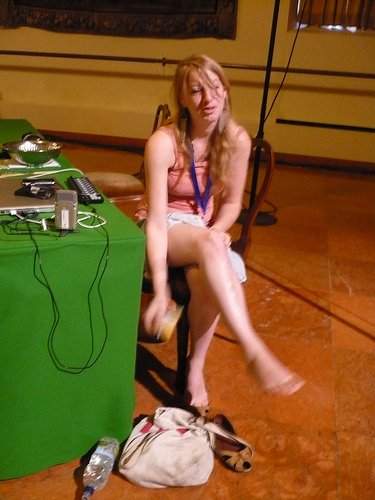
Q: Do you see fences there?
A: No, there are no fences.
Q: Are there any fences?
A: No, there are no fences.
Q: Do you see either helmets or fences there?
A: No, there are no fences or helmets.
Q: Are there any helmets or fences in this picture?
A: No, there are no fences or helmets.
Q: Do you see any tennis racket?
A: No, there are no rackets.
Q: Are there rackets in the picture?
A: No, there are no rackets.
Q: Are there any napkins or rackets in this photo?
A: No, there are no rackets or napkins.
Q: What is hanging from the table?
A: The cable is hanging from the table.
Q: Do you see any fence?
A: No, there are no fences.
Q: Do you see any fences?
A: No, there are no fences.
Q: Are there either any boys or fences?
A: No, there are no fences or boys.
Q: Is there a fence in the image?
A: No, there are no fences.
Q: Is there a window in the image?
A: Yes, there is a window.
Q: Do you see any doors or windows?
A: Yes, there is a window.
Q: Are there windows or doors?
A: Yes, there is a window.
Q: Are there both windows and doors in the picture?
A: No, there is a window but no doors.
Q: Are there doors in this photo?
A: No, there are no doors.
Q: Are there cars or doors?
A: No, there are no doors or cars.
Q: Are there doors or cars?
A: No, there are no doors or cars.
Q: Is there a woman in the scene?
A: Yes, there is a woman.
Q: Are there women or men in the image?
A: Yes, there is a woman.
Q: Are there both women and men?
A: No, there is a woman but no men.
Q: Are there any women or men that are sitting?
A: Yes, the woman is sitting.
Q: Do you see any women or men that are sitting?
A: Yes, the woman is sitting.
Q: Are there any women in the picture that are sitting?
A: Yes, there is a woman that is sitting.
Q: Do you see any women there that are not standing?
A: Yes, there is a woman that is sitting .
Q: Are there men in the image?
A: No, there are no men.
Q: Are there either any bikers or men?
A: No, there are no men or bikers.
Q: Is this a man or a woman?
A: This is a woman.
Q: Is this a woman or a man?
A: This is a woman.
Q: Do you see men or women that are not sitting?
A: No, there is a woman but she is sitting.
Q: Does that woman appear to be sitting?
A: Yes, the woman is sitting.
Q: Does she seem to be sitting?
A: Yes, the woman is sitting.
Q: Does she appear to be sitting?
A: Yes, the woman is sitting.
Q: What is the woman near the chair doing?
A: The woman is sitting.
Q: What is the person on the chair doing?
A: The woman is sitting.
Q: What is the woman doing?
A: The woman is sitting.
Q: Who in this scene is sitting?
A: The woman is sitting.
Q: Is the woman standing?
A: No, the woman is sitting.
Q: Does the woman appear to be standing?
A: No, the woman is sitting.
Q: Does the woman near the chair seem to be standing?
A: No, the woman is sitting.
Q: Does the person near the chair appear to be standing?
A: No, the woman is sitting.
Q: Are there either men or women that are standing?
A: No, there is a woman but she is sitting.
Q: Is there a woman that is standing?
A: No, there is a woman but she is sitting.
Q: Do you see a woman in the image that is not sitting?
A: No, there is a woman but she is sitting.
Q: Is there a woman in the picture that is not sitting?
A: No, there is a woman but she is sitting.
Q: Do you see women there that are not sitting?
A: No, there is a woman but she is sitting.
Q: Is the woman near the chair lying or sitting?
A: The woman is sitting.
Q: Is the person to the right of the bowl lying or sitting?
A: The woman is sitting.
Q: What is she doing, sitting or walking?
A: The woman is sitting.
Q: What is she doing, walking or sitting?
A: The woman is sitting.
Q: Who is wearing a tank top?
A: The woman is wearing a tank top.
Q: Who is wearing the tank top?
A: The woman is wearing a tank top.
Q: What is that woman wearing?
A: The woman is wearing a tank top.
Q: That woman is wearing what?
A: The woman is wearing a tank top.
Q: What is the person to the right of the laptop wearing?
A: The woman is wearing a tank top.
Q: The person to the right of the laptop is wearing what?
A: The woman is wearing a tank top.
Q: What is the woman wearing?
A: The woman is wearing a tank top.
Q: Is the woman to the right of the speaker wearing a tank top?
A: Yes, the woman is wearing a tank top.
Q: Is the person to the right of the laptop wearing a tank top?
A: Yes, the woman is wearing a tank top.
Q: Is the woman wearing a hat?
A: No, the woman is wearing a tank top.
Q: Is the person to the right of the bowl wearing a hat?
A: No, the woman is wearing a tank top.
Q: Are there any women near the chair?
A: Yes, there is a woman near the chair.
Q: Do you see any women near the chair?
A: Yes, there is a woman near the chair.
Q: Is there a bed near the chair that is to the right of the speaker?
A: No, there is a woman near the chair.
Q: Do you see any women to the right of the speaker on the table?
A: Yes, there is a woman to the right of the speaker.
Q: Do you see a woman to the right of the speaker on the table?
A: Yes, there is a woman to the right of the speaker.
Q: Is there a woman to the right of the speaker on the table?
A: Yes, there is a woman to the right of the speaker.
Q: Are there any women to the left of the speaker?
A: No, the woman is to the right of the speaker.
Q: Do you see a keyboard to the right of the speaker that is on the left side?
A: No, there is a woman to the right of the speaker.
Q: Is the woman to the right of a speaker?
A: Yes, the woman is to the right of a speaker.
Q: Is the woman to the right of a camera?
A: No, the woman is to the right of a speaker.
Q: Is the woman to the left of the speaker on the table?
A: No, the woman is to the right of the speaker.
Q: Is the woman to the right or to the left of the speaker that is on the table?
A: The woman is to the right of the speaker.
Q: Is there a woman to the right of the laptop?
A: Yes, there is a woman to the right of the laptop.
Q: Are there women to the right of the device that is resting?
A: Yes, there is a woman to the right of the laptop.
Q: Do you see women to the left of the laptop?
A: No, the woman is to the right of the laptop.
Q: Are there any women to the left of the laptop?
A: No, the woman is to the right of the laptop.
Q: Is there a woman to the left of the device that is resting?
A: No, the woman is to the right of the laptop.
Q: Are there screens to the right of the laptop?
A: No, there is a woman to the right of the laptop.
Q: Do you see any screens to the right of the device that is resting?
A: No, there is a woman to the right of the laptop.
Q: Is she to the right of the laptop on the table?
A: Yes, the woman is to the right of the laptop.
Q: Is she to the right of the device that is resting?
A: Yes, the woman is to the right of the laptop.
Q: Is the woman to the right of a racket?
A: No, the woman is to the right of the laptop.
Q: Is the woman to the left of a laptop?
A: No, the woman is to the right of a laptop.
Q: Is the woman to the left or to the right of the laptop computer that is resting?
A: The woman is to the right of the laptop.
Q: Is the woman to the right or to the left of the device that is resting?
A: The woman is to the right of the laptop.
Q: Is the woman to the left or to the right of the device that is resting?
A: The woman is to the right of the laptop.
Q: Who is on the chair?
A: The woman is on the chair.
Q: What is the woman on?
A: The woman is on the chair.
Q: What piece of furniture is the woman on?
A: The woman is on the chair.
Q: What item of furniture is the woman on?
A: The woman is on the chair.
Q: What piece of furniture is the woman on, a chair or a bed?
A: The woman is on a chair.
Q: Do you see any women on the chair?
A: Yes, there is a woman on the chair.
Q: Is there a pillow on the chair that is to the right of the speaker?
A: No, there is a woman on the chair.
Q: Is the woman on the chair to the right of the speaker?
A: Yes, the woman is on the chair.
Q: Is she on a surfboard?
A: No, the woman is on the chair.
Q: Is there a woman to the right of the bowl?
A: Yes, there is a woman to the right of the bowl.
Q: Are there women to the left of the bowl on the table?
A: No, the woman is to the right of the bowl.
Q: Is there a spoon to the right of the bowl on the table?
A: No, there is a woman to the right of the bowl.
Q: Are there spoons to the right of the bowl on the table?
A: No, there is a woman to the right of the bowl.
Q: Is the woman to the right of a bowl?
A: Yes, the woman is to the right of a bowl.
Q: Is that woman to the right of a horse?
A: No, the woman is to the right of a bowl.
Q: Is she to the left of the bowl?
A: No, the woman is to the right of the bowl.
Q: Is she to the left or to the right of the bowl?
A: The woman is to the right of the bowl.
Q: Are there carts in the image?
A: No, there are no carts.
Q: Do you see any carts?
A: No, there are no carts.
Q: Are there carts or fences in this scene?
A: No, there are no carts or fences.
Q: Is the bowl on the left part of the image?
A: Yes, the bowl is on the left of the image.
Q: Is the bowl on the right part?
A: No, the bowl is on the left of the image.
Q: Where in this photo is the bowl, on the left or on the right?
A: The bowl is on the left of the image.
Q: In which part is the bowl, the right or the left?
A: The bowl is on the left of the image.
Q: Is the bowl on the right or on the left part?
A: The bowl is on the left of the image.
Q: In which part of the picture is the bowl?
A: The bowl is on the left of the image.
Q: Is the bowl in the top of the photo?
A: Yes, the bowl is in the top of the image.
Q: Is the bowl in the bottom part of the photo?
A: No, the bowl is in the top of the image.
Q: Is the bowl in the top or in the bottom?
A: The bowl is in the top of the image.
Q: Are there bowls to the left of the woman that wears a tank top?
A: Yes, there is a bowl to the left of the woman.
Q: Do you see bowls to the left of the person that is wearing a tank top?
A: Yes, there is a bowl to the left of the woman.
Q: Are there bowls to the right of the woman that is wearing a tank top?
A: No, the bowl is to the left of the woman.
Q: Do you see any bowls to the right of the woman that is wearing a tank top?
A: No, the bowl is to the left of the woman.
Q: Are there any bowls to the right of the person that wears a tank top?
A: No, the bowl is to the left of the woman.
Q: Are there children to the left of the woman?
A: No, there is a bowl to the left of the woman.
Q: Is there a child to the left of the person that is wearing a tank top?
A: No, there is a bowl to the left of the woman.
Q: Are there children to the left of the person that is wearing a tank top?
A: No, there is a bowl to the left of the woman.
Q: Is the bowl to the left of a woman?
A: Yes, the bowl is to the left of a woman.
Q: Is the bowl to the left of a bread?
A: No, the bowl is to the left of a woman.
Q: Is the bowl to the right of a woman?
A: No, the bowl is to the left of a woman.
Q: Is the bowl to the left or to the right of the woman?
A: The bowl is to the left of the woman.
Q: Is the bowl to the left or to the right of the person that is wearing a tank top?
A: The bowl is to the left of the woman.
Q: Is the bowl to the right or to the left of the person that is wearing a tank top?
A: The bowl is to the left of the woman.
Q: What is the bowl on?
A: The bowl is on the table.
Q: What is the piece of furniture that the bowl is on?
A: The piece of furniture is a table.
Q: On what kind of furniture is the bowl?
A: The bowl is on the table.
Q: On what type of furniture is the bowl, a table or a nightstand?
A: The bowl is on a table.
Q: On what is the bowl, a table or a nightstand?
A: The bowl is on a table.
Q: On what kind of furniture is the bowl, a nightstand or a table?
A: The bowl is on a table.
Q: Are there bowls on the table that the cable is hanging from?
A: Yes, there is a bowl on the table.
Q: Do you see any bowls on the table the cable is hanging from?
A: Yes, there is a bowl on the table.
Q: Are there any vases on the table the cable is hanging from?
A: No, there is a bowl on the table.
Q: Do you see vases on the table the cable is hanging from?
A: No, there is a bowl on the table.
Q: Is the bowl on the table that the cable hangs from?
A: Yes, the bowl is on the table.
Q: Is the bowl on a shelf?
A: No, the bowl is on the table.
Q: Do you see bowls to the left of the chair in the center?
A: Yes, there is a bowl to the left of the chair.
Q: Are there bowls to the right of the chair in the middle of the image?
A: No, the bowl is to the left of the chair.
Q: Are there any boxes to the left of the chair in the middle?
A: No, there is a bowl to the left of the chair.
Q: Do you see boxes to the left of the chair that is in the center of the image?
A: No, there is a bowl to the left of the chair.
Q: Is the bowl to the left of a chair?
A: Yes, the bowl is to the left of a chair.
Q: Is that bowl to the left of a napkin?
A: No, the bowl is to the left of a chair.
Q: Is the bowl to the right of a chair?
A: No, the bowl is to the left of a chair.